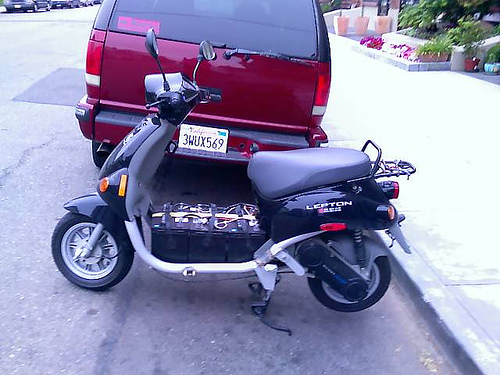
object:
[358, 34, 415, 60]
flowers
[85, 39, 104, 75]
light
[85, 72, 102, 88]
light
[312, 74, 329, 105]
light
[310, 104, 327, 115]
light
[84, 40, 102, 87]
rear light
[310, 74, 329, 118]
rear light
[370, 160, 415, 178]
wall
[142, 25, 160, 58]
mirror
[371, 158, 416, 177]
rack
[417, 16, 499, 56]
plants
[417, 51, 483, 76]
pots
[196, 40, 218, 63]
mirror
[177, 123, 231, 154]
license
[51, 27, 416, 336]
moped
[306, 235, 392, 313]
rear wheel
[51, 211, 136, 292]
tire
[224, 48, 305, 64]
windshield wiper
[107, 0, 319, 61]
rear window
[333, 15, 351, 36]
clay pot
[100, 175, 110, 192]
light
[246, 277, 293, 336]
kickstand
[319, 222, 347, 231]
reflector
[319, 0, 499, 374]
sidewalk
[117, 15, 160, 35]
sticker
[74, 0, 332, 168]
car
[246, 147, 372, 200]
seat